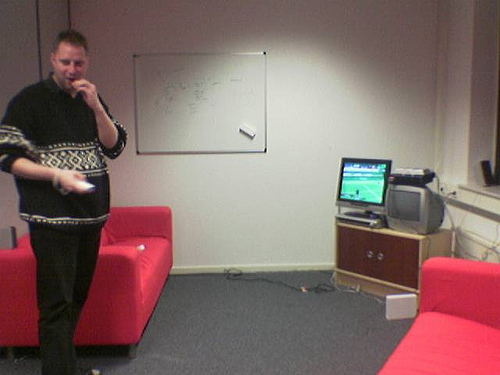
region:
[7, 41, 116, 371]
a man eating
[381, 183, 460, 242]
a blank television set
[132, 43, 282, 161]
a board with marker writing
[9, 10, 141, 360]
a man wearing black pants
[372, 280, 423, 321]
a Wii videogame system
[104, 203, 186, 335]
a red couch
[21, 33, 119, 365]
a man holding a wii controller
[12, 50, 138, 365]
a man in a black and white sweater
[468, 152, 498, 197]
grey and black computer speakers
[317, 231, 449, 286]
a brown and tan cabinet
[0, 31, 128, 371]
man standing next to a red sofa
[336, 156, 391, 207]
monitor screen sitting on the cabinet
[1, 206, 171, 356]
red sofa sitting in the corner of the room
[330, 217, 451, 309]
light brown cabinet with dark brown doors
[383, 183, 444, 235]
tv sitting on the wood cabinet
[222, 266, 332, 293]
black cord on the floor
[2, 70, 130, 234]
black and white sweater the man is wearing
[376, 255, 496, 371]
part of a fuchsia colored sofa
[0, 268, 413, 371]
gray carpet on the floor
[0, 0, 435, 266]
white wall with a sofa against it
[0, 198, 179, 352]
red colored sofa couch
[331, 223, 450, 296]
dark and light brown cabinet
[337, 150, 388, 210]
small flat screen tv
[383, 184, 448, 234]
older style grey tv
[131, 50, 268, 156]
white washable white board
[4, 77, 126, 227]
man wearing black sweater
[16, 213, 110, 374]
man wearing black pants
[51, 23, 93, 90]
man with short hair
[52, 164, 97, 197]
man holding remote control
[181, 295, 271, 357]
grey colored carpet flooring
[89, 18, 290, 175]
a board attached to the wall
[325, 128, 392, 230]
the television is on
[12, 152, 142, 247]
the man is holding a remote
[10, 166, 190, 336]
a red couch against the wall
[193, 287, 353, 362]
the floor is grey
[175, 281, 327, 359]
the floor is carpeted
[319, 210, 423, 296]
the doors are brown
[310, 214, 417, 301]
the doors are made of wood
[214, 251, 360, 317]
wires on the floor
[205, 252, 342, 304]
the wire is black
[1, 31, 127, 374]
man is holding wii mote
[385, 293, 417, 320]
white wii console on ground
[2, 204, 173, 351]
large red couch behind man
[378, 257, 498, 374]
large red couch beside wii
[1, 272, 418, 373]
grey carpet flooring is shown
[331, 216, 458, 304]
two toned wooden entertainment center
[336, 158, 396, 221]
large black computer monitor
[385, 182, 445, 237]
old grey tv on stand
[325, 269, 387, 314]
wii cords run on carpet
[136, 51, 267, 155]
dry erase board on wall